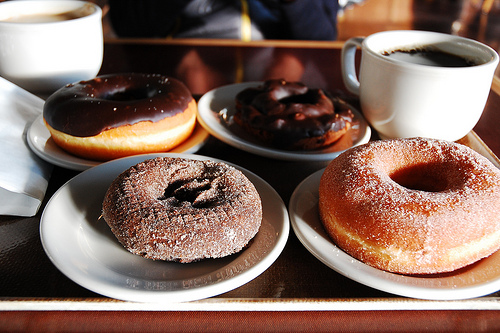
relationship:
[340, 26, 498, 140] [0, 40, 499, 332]
cup on table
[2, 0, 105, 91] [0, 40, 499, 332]
cup on table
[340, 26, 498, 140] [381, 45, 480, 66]
cup filled with dark coffee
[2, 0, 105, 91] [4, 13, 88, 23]
cup filled witth coffee and milk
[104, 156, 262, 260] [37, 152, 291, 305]
donut on a plate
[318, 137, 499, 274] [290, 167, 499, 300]
donut on a plate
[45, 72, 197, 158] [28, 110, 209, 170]
donut on a plate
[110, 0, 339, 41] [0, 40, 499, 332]
person sitting at table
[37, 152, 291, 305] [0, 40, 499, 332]
plate on table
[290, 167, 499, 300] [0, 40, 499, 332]
plate on table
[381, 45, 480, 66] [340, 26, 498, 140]
dark coffee in cup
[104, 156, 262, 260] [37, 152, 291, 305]
donut on plate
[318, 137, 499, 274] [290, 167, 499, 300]
donut on plate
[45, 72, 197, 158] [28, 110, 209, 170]
donut on plate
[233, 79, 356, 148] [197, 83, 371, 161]
donut on plate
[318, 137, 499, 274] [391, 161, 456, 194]
donut has hole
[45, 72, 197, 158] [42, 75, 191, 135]
donut has chocolate frosting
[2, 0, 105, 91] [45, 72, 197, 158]
cup behind donut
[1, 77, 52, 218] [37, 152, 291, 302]
napkin on plate